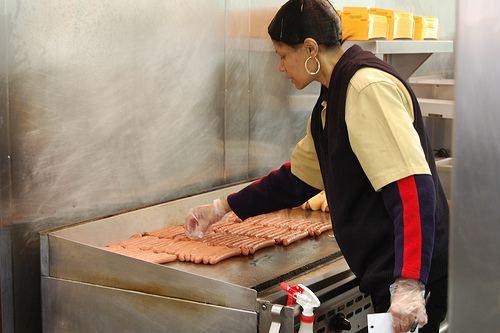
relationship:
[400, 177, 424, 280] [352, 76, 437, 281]
red stripe on a sleeve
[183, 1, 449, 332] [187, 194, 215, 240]
person wears gloves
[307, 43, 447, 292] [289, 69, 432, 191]
vest over t-shirt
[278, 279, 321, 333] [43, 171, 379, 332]
spray bottle by grill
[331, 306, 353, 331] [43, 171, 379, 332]
knob on grill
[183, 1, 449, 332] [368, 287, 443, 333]
person holding paper and pen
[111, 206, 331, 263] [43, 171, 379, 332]
hotdogs on grill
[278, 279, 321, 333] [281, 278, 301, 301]
spray bottle has a nozzle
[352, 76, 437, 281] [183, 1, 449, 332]
sleeve on person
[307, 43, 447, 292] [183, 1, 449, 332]
vest on person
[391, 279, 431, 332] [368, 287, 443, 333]
glove holding paper and pencil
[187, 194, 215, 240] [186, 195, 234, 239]
glove on right hand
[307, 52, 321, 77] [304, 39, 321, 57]
earring on ear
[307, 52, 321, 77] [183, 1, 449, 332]
earring on a person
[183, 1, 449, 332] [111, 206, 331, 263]
person arranges hotdogs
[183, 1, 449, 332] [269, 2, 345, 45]
person wears a hairnet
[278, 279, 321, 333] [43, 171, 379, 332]
spray bottle next to grill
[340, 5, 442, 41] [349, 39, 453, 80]
containers on a shelf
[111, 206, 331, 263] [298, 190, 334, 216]
hotdogs on buns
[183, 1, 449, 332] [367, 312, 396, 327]
person holds paper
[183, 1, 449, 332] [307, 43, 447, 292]
person wears a vest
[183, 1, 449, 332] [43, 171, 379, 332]
person cooking on a grill